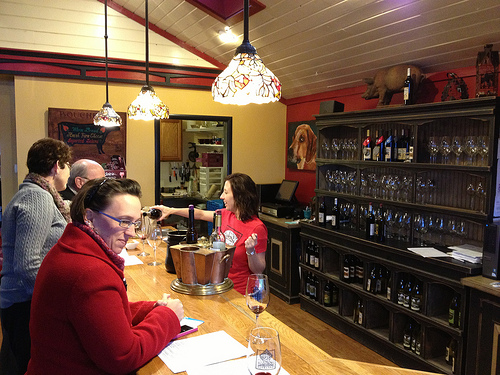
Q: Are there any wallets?
A: No, there are no wallets.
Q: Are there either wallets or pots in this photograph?
A: No, there are no wallets or pots.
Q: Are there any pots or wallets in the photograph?
A: No, there are no wallets or pots.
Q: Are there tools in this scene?
A: No, there are no tools.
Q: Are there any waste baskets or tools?
A: No, there are no tools or waste baskets.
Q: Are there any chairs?
A: No, there are no chairs.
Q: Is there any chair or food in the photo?
A: No, there are no chairs or food.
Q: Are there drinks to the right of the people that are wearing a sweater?
A: Yes, there is a drink to the right of the people.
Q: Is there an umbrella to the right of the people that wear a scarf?
A: No, there is a drink to the right of the people.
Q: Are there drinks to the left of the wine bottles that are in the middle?
A: Yes, there is a drink to the left of the wine bottles.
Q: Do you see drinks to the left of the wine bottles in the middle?
A: Yes, there is a drink to the left of the wine bottles.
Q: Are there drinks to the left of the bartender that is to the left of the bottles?
A: Yes, there is a drink to the left of the bartender.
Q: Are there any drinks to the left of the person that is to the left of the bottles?
A: Yes, there is a drink to the left of the bartender.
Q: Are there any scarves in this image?
A: Yes, there is a scarf.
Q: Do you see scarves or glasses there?
A: Yes, there is a scarf.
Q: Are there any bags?
A: No, there are no bags.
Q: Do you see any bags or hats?
A: No, there are no bags or hats.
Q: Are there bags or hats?
A: No, there are no bags or hats.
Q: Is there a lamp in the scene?
A: Yes, there is a lamp.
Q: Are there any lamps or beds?
A: Yes, there is a lamp.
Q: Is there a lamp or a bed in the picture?
A: Yes, there is a lamp.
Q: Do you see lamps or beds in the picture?
A: Yes, there is a lamp.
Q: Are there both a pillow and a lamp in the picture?
A: No, there is a lamp but no pillows.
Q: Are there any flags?
A: No, there are no flags.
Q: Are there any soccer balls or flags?
A: No, there are no flags or soccer balls.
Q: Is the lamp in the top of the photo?
A: Yes, the lamp is in the top of the image.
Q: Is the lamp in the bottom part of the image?
A: No, the lamp is in the top of the image.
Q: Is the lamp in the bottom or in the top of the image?
A: The lamp is in the top of the image.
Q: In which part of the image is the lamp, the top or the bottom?
A: The lamp is in the top of the image.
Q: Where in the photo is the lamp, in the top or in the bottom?
A: The lamp is in the top of the image.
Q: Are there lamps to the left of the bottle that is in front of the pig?
A: Yes, there is a lamp to the left of the bottle.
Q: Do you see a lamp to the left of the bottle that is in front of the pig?
A: Yes, there is a lamp to the left of the bottle.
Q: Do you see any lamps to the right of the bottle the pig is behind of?
A: No, the lamp is to the left of the bottle.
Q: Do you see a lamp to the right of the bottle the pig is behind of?
A: No, the lamp is to the left of the bottle.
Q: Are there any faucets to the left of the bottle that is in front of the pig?
A: No, there is a lamp to the left of the bottle.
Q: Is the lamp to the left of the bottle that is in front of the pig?
A: Yes, the lamp is to the left of the bottle.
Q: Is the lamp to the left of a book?
A: No, the lamp is to the left of the bottle.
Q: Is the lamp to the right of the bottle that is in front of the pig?
A: No, the lamp is to the left of the bottle.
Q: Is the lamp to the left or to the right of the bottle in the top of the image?
A: The lamp is to the left of the bottle.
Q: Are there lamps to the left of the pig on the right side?
A: Yes, there is a lamp to the left of the pig.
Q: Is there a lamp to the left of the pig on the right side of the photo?
A: Yes, there is a lamp to the left of the pig.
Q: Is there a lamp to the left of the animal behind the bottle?
A: Yes, there is a lamp to the left of the pig.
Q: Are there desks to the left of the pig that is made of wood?
A: No, there is a lamp to the left of the pig.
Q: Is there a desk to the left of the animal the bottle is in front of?
A: No, there is a lamp to the left of the pig.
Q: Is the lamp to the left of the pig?
A: Yes, the lamp is to the left of the pig.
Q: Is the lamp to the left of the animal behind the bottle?
A: Yes, the lamp is to the left of the pig.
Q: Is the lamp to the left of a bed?
A: No, the lamp is to the left of the pig.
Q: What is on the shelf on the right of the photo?
A: The glasses are on the shelf.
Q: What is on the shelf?
A: The glasses are on the shelf.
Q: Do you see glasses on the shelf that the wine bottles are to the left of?
A: Yes, there are glasses on the shelf.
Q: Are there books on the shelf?
A: No, there are glasses on the shelf.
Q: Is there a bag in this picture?
A: No, there are no bags.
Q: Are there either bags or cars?
A: No, there are no bags or cars.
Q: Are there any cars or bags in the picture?
A: No, there are no bags or cars.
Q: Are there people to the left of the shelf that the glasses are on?
A: Yes, there are people to the left of the shelf.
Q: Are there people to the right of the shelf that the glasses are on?
A: No, the people are to the left of the shelf.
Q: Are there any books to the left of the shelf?
A: No, there are people to the left of the shelf.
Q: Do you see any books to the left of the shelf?
A: No, there are people to the left of the shelf.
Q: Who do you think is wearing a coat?
A: The people are wearing a coat.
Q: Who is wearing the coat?
A: The people are wearing a coat.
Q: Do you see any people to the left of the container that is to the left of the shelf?
A: Yes, there are people to the left of the container.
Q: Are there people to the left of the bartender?
A: Yes, there are people to the left of the bartender.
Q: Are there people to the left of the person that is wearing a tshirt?
A: Yes, there are people to the left of the bartender.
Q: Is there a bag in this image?
A: No, there are no bags.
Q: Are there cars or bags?
A: No, there are no bags or cars.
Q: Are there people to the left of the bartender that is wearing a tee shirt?
A: Yes, there are people to the left of the bartender.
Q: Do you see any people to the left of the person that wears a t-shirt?
A: Yes, there are people to the left of the bartender.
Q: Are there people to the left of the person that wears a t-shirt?
A: Yes, there are people to the left of the bartender.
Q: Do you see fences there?
A: No, there are no fences.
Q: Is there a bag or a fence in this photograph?
A: No, there are no fences or bags.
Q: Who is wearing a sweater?
A: The people are wearing a sweater.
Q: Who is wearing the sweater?
A: The people are wearing a sweater.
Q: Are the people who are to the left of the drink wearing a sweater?
A: Yes, the people are wearing a sweater.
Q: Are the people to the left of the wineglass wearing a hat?
A: No, the people are wearing a sweater.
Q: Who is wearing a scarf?
A: The people are wearing a scarf.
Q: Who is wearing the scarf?
A: The people are wearing a scarf.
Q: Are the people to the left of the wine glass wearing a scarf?
A: Yes, the people are wearing a scarf.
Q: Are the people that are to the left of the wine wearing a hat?
A: No, the people are wearing a scarf.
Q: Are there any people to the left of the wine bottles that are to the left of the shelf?
A: Yes, there are people to the left of the wine bottles.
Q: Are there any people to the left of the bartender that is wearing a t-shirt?
A: Yes, there are people to the left of the bartender.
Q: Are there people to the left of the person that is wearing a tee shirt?
A: Yes, there are people to the left of the bartender.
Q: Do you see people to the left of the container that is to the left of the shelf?
A: Yes, there are people to the left of the container.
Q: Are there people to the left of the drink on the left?
A: Yes, there are people to the left of the drink.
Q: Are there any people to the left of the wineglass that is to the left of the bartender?
A: Yes, there are people to the left of the wineglass.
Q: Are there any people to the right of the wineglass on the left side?
A: No, the people are to the left of the wine glass.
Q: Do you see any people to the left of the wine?
A: Yes, there are people to the left of the wine.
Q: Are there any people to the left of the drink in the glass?
A: Yes, there are people to the left of the wine.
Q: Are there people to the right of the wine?
A: No, the people are to the left of the wine.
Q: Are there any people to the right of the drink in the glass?
A: No, the people are to the left of the wine.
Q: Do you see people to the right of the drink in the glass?
A: No, the people are to the left of the wine.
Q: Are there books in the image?
A: No, there are no books.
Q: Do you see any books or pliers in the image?
A: No, there are no books or pliers.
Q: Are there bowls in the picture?
A: No, there are no bowls.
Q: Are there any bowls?
A: No, there are no bowls.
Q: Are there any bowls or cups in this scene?
A: No, there are no bowls or cups.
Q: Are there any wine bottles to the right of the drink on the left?
A: Yes, there are wine bottles to the right of the drink.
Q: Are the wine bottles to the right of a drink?
A: Yes, the wine bottles are to the right of a drink.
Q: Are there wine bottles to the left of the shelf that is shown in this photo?
A: Yes, there are wine bottles to the left of the shelf.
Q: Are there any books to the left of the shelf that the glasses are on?
A: No, there are wine bottles to the left of the shelf.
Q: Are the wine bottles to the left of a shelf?
A: Yes, the wine bottles are to the left of a shelf.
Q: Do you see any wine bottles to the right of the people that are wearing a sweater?
A: Yes, there are wine bottles to the right of the people.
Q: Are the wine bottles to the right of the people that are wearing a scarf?
A: Yes, the wine bottles are to the right of the people.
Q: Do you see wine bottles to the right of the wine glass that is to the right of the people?
A: Yes, there are wine bottles to the right of the wine glass.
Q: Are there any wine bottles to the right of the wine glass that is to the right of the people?
A: Yes, there are wine bottles to the right of the wine glass.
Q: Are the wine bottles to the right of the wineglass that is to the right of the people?
A: Yes, the wine bottles are to the right of the wineglass.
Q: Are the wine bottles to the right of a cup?
A: No, the wine bottles are to the right of the wineglass.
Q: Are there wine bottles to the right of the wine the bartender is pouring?
A: Yes, there are wine bottles to the right of the wine.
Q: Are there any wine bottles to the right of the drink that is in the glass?
A: Yes, there are wine bottles to the right of the wine.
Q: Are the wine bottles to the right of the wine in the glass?
A: Yes, the wine bottles are to the right of the wine.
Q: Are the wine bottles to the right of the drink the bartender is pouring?
A: Yes, the wine bottles are to the right of the wine.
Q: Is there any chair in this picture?
A: No, there are no chairs.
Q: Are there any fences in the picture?
A: No, there are no fences.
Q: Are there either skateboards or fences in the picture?
A: No, there are no fences or skateboards.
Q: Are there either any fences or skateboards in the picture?
A: No, there are no fences or skateboards.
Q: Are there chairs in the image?
A: No, there are no chairs.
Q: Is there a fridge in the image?
A: No, there are no refrigerators.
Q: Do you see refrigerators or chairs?
A: No, there are no refrigerators or chairs.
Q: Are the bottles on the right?
A: Yes, the bottles are on the right of the image.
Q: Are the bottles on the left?
A: No, the bottles are on the right of the image.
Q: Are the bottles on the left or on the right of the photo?
A: The bottles are on the right of the image.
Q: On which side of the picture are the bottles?
A: The bottles are on the right of the image.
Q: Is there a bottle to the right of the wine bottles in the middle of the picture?
A: Yes, there are bottles to the right of the wine bottles.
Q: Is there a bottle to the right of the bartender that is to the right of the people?
A: Yes, there are bottles to the right of the bartender.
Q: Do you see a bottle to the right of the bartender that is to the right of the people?
A: Yes, there are bottles to the right of the bartender.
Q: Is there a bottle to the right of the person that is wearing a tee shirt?
A: Yes, there are bottles to the right of the bartender.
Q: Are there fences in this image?
A: No, there are no fences.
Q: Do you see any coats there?
A: Yes, there is a coat.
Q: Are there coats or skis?
A: Yes, there is a coat.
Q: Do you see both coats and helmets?
A: No, there is a coat but no helmets.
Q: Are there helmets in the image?
A: No, there are no helmets.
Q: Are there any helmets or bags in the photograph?
A: No, there are no helmets or bags.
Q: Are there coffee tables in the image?
A: No, there are no coffee tables.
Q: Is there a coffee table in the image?
A: No, there are no coffee tables.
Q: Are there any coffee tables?
A: No, there are no coffee tables.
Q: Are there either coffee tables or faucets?
A: No, there are no coffee tables or faucets.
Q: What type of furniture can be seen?
A: The furniture is a shelf.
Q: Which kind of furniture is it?
A: The piece of furniture is a shelf.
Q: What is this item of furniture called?
A: This is a shelf.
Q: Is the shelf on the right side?
A: Yes, the shelf is on the right of the image.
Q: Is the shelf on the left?
A: No, the shelf is on the right of the image.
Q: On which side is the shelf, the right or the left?
A: The shelf is on the right of the image.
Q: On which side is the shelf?
A: The shelf is on the right of the image.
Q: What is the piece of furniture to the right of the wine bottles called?
A: The piece of furniture is a shelf.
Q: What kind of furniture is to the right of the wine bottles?
A: The piece of furniture is a shelf.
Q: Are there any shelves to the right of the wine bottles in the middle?
A: Yes, there is a shelf to the right of the wine bottles.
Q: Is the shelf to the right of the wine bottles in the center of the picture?
A: Yes, the shelf is to the right of the wine bottles.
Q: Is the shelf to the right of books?
A: No, the shelf is to the right of the wine bottles.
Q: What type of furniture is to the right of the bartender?
A: The piece of furniture is a shelf.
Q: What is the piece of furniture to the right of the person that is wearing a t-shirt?
A: The piece of furniture is a shelf.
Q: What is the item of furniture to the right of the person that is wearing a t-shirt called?
A: The piece of furniture is a shelf.